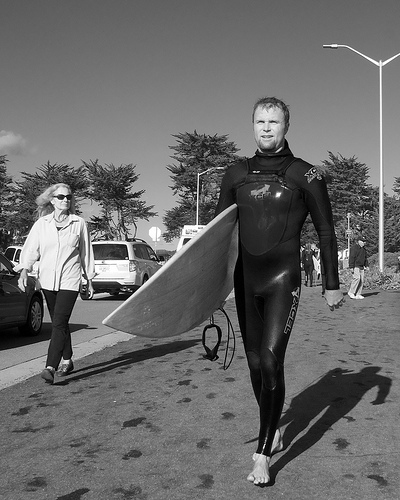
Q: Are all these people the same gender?
A: No, they are both male and female.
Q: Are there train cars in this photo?
A: No, there are no train cars.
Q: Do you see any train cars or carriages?
A: No, there are no train cars or carriages.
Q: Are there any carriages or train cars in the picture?
A: No, there are no train cars or carriages.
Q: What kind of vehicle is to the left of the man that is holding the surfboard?
A: The vehicle is a car.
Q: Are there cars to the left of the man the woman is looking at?
A: Yes, there is a car to the left of the man.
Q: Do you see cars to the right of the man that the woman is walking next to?
A: No, the car is to the left of the man.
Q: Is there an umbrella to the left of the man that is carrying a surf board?
A: No, there is a car to the left of the man.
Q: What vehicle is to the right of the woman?
A: The vehicle is a car.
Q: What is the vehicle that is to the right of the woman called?
A: The vehicle is a car.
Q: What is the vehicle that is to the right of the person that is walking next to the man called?
A: The vehicle is a car.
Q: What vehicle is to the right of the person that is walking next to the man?
A: The vehicle is a car.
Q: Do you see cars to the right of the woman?
A: Yes, there is a car to the right of the woman.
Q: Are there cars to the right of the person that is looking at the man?
A: Yes, there is a car to the right of the woman.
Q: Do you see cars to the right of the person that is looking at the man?
A: Yes, there is a car to the right of the woman.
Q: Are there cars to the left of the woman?
A: No, the car is to the right of the woman.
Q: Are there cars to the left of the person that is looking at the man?
A: No, the car is to the right of the woman.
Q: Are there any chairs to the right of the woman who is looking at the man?
A: No, there is a car to the right of the woman.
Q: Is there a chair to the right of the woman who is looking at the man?
A: No, there is a car to the right of the woman.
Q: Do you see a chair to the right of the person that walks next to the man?
A: No, there is a car to the right of the woman.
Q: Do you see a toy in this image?
A: No, there are no toys.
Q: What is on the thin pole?
A: The street light is on the pole.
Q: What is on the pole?
A: The street light is on the pole.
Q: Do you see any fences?
A: No, there are no fences.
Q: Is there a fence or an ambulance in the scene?
A: No, there are no fences or ambulances.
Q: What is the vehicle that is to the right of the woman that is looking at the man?
A: The vehicle is a van.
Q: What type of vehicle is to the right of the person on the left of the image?
A: The vehicle is a van.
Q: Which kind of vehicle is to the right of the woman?
A: The vehicle is a van.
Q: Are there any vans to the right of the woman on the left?
A: Yes, there is a van to the right of the woman.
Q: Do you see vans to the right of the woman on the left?
A: Yes, there is a van to the right of the woman.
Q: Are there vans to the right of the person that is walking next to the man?
A: Yes, there is a van to the right of the woman.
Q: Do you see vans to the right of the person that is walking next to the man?
A: Yes, there is a van to the right of the woman.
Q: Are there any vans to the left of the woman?
A: No, the van is to the right of the woman.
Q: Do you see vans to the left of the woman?
A: No, the van is to the right of the woman.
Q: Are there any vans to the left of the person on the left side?
A: No, the van is to the right of the woman.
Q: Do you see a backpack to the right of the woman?
A: No, there is a van to the right of the woman.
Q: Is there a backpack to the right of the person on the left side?
A: No, there is a van to the right of the woman.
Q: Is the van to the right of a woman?
A: Yes, the van is to the right of a woman.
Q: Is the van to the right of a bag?
A: No, the van is to the right of a woman.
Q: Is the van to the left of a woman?
A: No, the van is to the right of a woman.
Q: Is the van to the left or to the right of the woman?
A: The van is to the right of the woman.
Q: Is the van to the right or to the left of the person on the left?
A: The van is to the right of the woman.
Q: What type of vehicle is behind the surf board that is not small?
A: The vehicle is a van.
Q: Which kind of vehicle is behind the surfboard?
A: The vehicle is a van.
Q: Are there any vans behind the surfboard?
A: Yes, there is a van behind the surfboard.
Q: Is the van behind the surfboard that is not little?
A: Yes, the van is behind the surf board.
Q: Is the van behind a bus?
A: No, the van is behind the surf board.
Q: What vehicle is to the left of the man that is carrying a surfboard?
A: The vehicle is a van.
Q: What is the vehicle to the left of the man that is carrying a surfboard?
A: The vehicle is a van.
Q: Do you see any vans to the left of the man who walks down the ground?
A: Yes, there is a van to the left of the man.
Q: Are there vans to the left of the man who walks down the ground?
A: Yes, there is a van to the left of the man.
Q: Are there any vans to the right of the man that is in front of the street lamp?
A: No, the van is to the left of the man.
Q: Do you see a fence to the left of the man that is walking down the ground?
A: No, there is a van to the left of the man.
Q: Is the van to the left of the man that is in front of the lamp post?
A: Yes, the van is to the left of the man.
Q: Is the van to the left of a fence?
A: No, the van is to the left of the man.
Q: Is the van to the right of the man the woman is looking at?
A: No, the van is to the left of the man.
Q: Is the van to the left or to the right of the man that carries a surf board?
A: The van is to the left of the man.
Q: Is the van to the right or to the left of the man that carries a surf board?
A: The van is to the left of the man.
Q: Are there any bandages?
A: No, there are no bandages.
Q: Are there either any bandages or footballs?
A: No, there are no bandages or footballs.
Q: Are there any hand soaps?
A: No, there are no hand soaps.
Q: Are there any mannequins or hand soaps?
A: No, there are no hand soaps or mannequins.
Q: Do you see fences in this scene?
A: No, there are no fences.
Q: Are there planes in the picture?
A: No, there are no planes.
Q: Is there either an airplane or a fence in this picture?
A: No, there are no airplanes or fences.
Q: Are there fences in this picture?
A: No, there are no fences.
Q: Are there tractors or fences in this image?
A: No, there are no fences or tractors.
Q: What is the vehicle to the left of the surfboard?
A: The vehicle is a car.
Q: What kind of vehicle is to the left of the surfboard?
A: The vehicle is a car.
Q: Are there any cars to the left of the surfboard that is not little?
A: Yes, there is a car to the left of the surfboard.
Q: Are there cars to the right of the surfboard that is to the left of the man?
A: No, the car is to the left of the surfboard.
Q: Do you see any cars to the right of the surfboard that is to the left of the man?
A: No, the car is to the left of the surfboard.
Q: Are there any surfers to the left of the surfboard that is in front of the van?
A: No, there is a car to the left of the surfboard.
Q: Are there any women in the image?
A: Yes, there is a woman.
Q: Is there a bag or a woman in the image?
A: Yes, there is a woman.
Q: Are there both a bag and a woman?
A: No, there is a woman but no bags.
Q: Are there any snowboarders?
A: No, there are no snowboarders.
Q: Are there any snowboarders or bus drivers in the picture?
A: No, there are no snowboarders or bus drivers.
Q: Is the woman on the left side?
A: Yes, the woman is on the left of the image.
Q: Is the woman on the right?
A: No, the woman is on the left of the image.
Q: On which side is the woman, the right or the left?
A: The woman is on the left of the image.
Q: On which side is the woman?
A: The woman is on the left of the image.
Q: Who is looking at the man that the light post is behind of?
A: The woman is looking at the man.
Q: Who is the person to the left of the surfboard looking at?
A: The woman is looking at the man.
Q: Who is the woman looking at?
A: The woman is looking at the man.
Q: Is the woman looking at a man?
A: Yes, the woman is looking at a man.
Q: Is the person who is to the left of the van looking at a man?
A: Yes, the woman is looking at a man.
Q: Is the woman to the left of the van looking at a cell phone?
A: No, the woman is looking at a man.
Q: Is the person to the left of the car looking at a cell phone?
A: No, the woman is looking at a man.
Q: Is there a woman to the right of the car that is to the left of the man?
A: No, the woman is to the left of the car.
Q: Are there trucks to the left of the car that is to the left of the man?
A: No, there is a woman to the left of the car.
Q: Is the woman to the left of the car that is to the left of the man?
A: Yes, the woman is to the left of the car.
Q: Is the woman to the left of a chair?
A: No, the woman is to the left of the car.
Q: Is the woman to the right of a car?
A: No, the woman is to the left of a car.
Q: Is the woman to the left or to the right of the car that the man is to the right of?
A: The woman is to the left of the car.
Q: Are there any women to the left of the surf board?
A: Yes, there is a woman to the left of the surf board.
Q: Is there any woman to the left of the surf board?
A: Yes, there is a woman to the left of the surf board.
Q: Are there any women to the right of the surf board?
A: No, the woman is to the left of the surf board.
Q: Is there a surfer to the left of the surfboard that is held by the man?
A: No, there is a woman to the left of the surfboard.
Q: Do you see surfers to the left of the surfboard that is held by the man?
A: No, there is a woman to the left of the surfboard.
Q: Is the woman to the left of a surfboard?
A: Yes, the woman is to the left of a surfboard.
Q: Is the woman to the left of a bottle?
A: No, the woman is to the left of a surfboard.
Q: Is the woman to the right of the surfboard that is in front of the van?
A: No, the woman is to the left of the surf board.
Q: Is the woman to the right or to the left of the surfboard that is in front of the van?
A: The woman is to the left of the surf board.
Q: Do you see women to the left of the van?
A: Yes, there is a woman to the left of the van.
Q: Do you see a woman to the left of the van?
A: Yes, there is a woman to the left of the van.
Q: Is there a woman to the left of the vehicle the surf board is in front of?
A: Yes, there is a woman to the left of the van.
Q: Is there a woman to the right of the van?
A: No, the woman is to the left of the van.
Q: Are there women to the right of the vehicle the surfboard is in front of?
A: No, the woman is to the left of the van.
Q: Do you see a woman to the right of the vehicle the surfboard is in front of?
A: No, the woman is to the left of the van.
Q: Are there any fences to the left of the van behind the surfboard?
A: No, there is a woman to the left of the van.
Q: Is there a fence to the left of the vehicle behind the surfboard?
A: No, there is a woman to the left of the van.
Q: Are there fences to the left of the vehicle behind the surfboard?
A: No, there is a woman to the left of the van.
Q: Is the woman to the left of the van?
A: Yes, the woman is to the left of the van.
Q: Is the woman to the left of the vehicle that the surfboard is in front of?
A: Yes, the woman is to the left of the van.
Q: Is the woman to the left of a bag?
A: No, the woman is to the left of the van.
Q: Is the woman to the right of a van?
A: No, the woman is to the left of a van.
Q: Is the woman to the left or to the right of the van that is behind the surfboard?
A: The woman is to the left of the van.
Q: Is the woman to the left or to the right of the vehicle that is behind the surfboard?
A: The woman is to the left of the van.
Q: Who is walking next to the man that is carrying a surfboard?
A: The woman is walking next to the man.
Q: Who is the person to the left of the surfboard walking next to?
A: The woman is walking next to the man.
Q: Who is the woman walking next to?
A: The woman is walking next to the man.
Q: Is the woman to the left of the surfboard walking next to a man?
A: Yes, the woman is walking next to a man.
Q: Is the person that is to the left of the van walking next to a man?
A: Yes, the woman is walking next to a man.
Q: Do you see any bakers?
A: No, there are no bakers.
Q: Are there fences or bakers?
A: No, there are no bakers or fences.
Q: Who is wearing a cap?
A: The man is wearing a cap.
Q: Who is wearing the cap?
A: The man is wearing a cap.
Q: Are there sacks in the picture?
A: No, there are no sacks.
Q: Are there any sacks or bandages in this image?
A: No, there are no sacks or bandages.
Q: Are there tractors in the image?
A: No, there are no tractors.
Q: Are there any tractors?
A: No, there are no tractors.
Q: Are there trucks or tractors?
A: No, there are no tractors or trucks.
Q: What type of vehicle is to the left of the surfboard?
A: The vehicle is a car.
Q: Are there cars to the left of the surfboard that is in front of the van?
A: Yes, there is a car to the left of the surfboard.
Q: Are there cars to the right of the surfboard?
A: No, the car is to the left of the surfboard.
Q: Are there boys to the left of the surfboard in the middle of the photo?
A: No, there is a car to the left of the surf board.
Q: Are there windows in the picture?
A: Yes, there is a window.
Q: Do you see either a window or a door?
A: Yes, there is a window.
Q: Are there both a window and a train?
A: No, there is a window but no trains.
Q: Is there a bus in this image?
A: No, there are no buses.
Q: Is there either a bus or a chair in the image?
A: No, there are no buses or chairs.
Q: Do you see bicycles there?
A: No, there are no bicycles.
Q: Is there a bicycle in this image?
A: No, there are no bicycles.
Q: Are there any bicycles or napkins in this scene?
A: No, there are no bicycles or napkins.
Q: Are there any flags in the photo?
A: No, there are no flags.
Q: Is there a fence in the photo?
A: No, there are no fences.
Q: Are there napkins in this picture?
A: No, there are no napkins.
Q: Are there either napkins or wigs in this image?
A: No, there are no napkins or wigs.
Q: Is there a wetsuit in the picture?
A: Yes, there is a wetsuit.